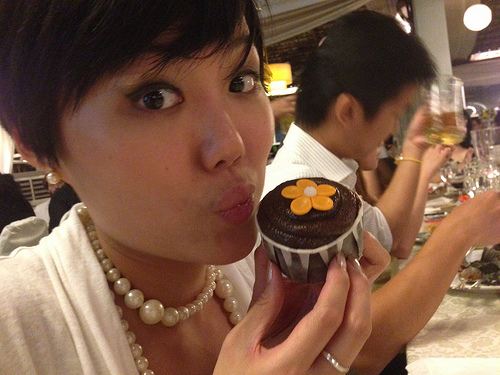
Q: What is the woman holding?
A: A cupcake.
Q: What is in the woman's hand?
A: A cupcake.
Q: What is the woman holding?
A: A cupcake.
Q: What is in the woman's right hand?
A: A cupcake.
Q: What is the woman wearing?
A: A necklace.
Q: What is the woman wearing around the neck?
A: Pearl necklaces.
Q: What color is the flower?
A: Yellow.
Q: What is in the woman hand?
A: A cupcake.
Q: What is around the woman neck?
A: Pearl necklace.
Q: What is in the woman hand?
A: A cupcake.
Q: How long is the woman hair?
A: Short.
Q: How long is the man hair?
A: Short.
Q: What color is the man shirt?
A: White.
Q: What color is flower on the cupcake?
A: Yellow.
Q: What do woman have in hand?
A: Cupcake.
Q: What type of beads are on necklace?
A: Pearls.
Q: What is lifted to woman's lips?
A: Cupcake.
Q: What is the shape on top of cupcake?
A: Flower.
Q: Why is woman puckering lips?
A: Kiss cupcake.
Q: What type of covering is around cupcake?
A: Paper.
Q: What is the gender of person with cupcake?
A: Female.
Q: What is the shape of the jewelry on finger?
A: Round.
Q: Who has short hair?
A: Woman and man.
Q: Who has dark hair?
A: Woman and man.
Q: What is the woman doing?
A: Posing.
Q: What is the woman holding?
A: Cupcake.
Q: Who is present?
A: A woman.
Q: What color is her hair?
A: Black.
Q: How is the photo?
A: Blurry.